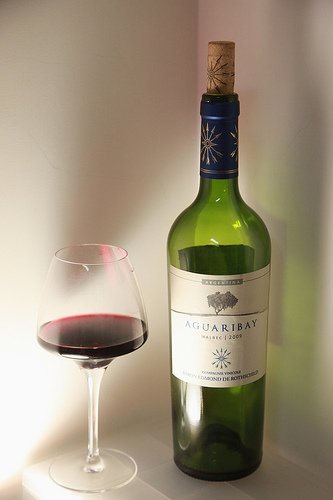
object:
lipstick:
[100, 245, 114, 271]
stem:
[83, 370, 104, 462]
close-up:
[0, 0, 333, 500]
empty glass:
[35, 242, 149, 492]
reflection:
[183, 382, 202, 424]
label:
[199, 116, 238, 180]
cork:
[205, 40, 235, 94]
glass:
[37, 242, 148, 491]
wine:
[34, 312, 149, 367]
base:
[48, 448, 139, 494]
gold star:
[211, 346, 232, 369]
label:
[169, 263, 269, 389]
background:
[0, 1, 331, 500]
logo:
[206, 291, 238, 315]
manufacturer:
[185, 318, 258, 331]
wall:
[198, 0, 333, 490]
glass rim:
[52, 243, 128, 265]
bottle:
[164, 91, 272, 483]